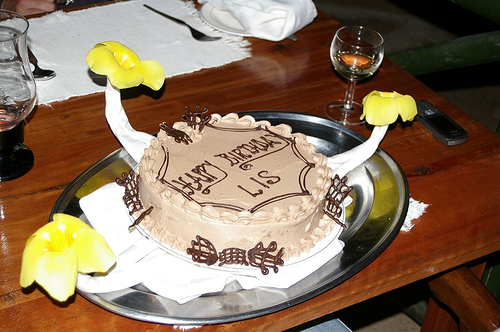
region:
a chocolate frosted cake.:
[104, 89, 364, 270]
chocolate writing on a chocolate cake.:
[158, 125, 320, 205]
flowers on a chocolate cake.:
[14, 208, 134, 309]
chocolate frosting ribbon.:
[295, 160, 340, 222]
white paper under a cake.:
[61, 116, 393, 311]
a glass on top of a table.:
[312, 16, 412, 151]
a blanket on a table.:
[0, 0, 260, 116]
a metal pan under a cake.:
[49, 105, 430, 330]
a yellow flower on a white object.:
[320, 80, 435, 177]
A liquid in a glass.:
[335, 50, 375, 73]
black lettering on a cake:
[171, 131, 301, 208]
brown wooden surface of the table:
[438, 177, 499, 213]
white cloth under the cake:
[126, 255, 228, 295]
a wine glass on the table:
[331, 30, 386, 133]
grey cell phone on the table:
[413, 99, 475, 150]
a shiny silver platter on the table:
[95, 286, 283, 326]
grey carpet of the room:
[361, 311, 401, 330]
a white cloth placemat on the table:
[24, 12, 245, 87]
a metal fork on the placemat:
[139, 0, 229, 54]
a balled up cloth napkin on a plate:
[224, 0, 316, 43]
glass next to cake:
[314, 23, 399, 103]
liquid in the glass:
[328, 45, 388, 86]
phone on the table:
[411, 89, 462, 157]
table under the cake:
[440, 161, 484, 206]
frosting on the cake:
[167, 120, 297, 229]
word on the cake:
[172, 148, 232, 207]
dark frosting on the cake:
[133, 110, 315, 247]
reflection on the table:
[249, 46, 309, 95]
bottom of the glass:
[314, 75, 371, 128]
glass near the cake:
[1, 7, 54, 123]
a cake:
[146, 124, 345, 245]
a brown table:
[423, 162, 496, 223]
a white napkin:
[165, 260, 222, 303]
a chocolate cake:
[143, 115, 325, 239]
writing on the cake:
[173, 121, 321, 215]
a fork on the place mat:
[181, 24, 226, 54]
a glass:
[330, 23, 385, 80]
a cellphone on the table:
[418, 98, 478, 151]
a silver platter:
[177, 299, 211, 321]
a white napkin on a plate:
[238, 1, 303, 33]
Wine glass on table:
[326, 18, 384, 124]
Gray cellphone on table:
[404, 92, 469, 148]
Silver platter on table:
[33, 112, 412, 322]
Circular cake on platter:
[117, 112, 357, 268]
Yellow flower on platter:
[72, 39, 164, 172]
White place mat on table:
[4, 0, 261, 97]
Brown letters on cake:
[235, 169, 282, 200]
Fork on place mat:
[139, 0, 221, 50]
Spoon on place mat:
[18, 35, 58, 86]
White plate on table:
[194, 2, 263, 42]